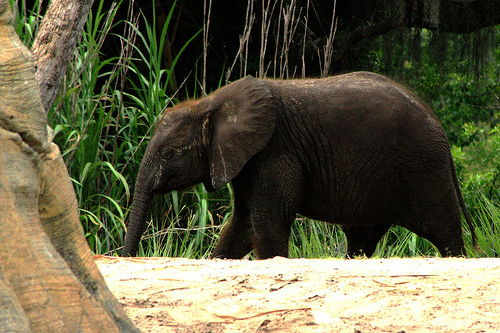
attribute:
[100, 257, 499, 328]
ground — beige, tan, brown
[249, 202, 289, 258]
leg — gray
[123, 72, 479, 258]
elephant — walking, brown, wrinkled, fuzzy, standing, grown, scared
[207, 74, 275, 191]
ear — flat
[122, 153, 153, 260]
trunk — long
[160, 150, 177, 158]
eye — small, dark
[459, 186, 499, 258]
grass — tall, high, green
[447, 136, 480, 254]
tail — gray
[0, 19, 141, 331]
stump — brown, large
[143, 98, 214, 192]
head — brown